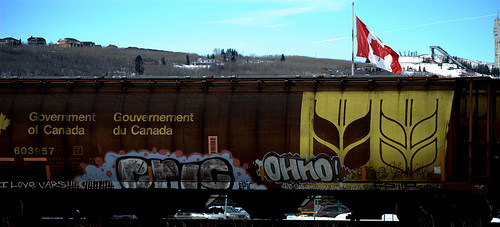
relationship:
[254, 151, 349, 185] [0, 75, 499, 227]
graffiti painted on train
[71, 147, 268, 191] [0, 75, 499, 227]
graffiti painted on train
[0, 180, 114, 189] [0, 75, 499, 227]
graffiti painted on train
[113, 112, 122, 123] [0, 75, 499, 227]
letter painted on train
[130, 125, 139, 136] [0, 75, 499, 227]
letter painted on train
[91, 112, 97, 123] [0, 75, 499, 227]
letter painted on train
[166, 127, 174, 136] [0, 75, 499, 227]
letter painted on train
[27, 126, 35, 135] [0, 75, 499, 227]
letter painted on train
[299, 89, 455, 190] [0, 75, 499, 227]
picture painted on train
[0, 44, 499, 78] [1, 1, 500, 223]
mountain inside of background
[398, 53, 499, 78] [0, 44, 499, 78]
snow on top of mountain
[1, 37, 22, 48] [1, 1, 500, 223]
building inside of background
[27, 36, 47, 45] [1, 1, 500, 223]
building inside of background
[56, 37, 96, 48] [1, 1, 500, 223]
building inside of background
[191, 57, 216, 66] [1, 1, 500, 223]
building inside of background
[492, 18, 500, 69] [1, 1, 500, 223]
building inside of background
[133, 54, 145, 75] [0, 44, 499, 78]
tree on top of mountain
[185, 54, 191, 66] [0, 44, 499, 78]
tree on top of mountain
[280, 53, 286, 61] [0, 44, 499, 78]
tree on top of mountain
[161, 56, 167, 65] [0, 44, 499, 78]
tree on top of mountain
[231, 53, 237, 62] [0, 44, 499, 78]
tree on top of mountain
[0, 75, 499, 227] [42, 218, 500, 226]
train on top of tracks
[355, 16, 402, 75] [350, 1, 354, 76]
flag attached on pole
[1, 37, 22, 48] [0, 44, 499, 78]
building on top of mountain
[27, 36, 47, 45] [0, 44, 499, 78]
building on top of mountain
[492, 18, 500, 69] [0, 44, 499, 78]
building on top of mountain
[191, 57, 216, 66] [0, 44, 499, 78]
building on top of mountain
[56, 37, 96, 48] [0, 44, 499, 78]
building on top of mountain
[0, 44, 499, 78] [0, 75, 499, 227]
mountain behind train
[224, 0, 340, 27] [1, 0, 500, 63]
cloud floating in sky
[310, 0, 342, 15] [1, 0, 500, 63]
cloud floating in sky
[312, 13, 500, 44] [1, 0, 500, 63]
cloud floating in sky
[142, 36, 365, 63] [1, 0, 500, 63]
cloud floating in sky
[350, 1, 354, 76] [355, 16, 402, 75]
pole has flag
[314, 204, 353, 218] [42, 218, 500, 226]
car behind tracks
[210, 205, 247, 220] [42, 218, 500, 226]
car behind tracks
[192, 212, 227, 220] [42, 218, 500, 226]
car behind tracks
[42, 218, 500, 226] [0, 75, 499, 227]
tracks are for train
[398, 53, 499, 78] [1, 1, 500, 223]
snow inside of background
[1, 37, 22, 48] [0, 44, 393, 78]
building next to field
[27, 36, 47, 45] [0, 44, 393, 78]
building next to field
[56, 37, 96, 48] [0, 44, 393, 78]
building next to field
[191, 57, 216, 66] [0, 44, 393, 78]
building next to field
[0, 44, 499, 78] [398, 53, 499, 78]
mountain has snow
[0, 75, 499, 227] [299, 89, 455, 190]
train has picture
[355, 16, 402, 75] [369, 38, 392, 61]
flag has leaf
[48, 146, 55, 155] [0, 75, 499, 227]
number painted on train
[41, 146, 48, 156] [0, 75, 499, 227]
number painted on train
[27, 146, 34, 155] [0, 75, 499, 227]
number painted on train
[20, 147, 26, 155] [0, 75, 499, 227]
number painted on train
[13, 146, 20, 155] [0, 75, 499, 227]
number painted on train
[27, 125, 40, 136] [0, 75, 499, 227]
word painted on train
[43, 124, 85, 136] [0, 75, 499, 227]
word painted on train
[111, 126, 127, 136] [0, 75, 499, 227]
word painted on train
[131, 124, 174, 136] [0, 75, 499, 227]
word painted on train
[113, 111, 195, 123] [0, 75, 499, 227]
word painted on train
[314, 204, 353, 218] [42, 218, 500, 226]
car beyond tracks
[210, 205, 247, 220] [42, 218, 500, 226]
car beyond tracks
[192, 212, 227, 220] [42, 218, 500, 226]
car beyond tracks